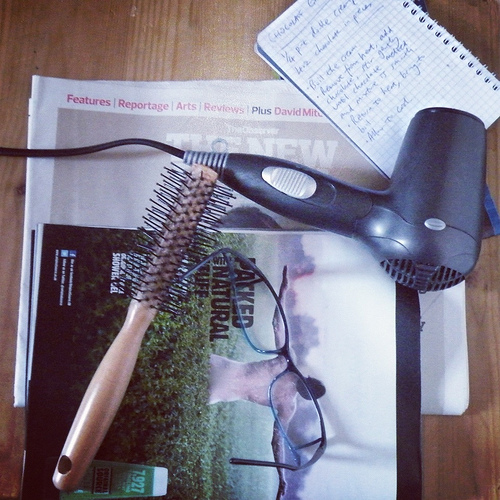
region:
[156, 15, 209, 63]
Small part of a wooden table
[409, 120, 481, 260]
Top black part of the hair blow dryer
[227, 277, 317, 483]
Blue and black glasses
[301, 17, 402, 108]
Writings on a small white notebook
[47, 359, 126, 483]
Bottom part of brush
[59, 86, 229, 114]
Red writings on the magazine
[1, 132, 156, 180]
Black cord of the hair blow dryer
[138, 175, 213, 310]
Top part of the tan brush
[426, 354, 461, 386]
White part of the magazine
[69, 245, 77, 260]
Facebook logo on magazines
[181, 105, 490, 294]
a black hair dryer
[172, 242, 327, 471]
a pair of black eyeglasses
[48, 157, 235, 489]
a brown hair brush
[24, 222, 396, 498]
a print magazine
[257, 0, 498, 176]
a small spiral note pad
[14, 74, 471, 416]
a folded print newspaper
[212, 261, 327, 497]
image of a naked man in bushes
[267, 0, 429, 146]
handwritten notes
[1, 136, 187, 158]
a black electric cord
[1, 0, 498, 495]
a brown table top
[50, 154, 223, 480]
Brown Hairbrush with black brissles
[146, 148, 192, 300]
Black brissles on hairbrush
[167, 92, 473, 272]
Black blowdryer with grey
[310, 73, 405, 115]
Blue ink writting on notepad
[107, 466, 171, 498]
Green numbers on magezine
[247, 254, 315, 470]
Blue prescription glasses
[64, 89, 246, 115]
Red Letters on magezine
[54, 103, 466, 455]
Person items on newspaper and magezine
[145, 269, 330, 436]
Half naked man on magezine cover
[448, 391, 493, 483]
Brown woodgrain on desk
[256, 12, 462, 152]
notes in a notebook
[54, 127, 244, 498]
brush on the table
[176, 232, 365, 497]
pair of blue glasses on the table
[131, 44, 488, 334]
black blow-dryer on the table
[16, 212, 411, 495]
magazine on the table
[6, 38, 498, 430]
newspaper on the table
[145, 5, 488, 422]
notebook on the table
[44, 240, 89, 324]
logos on the magazine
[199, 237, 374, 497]
man on the front of the magazine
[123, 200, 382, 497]
glasses on the top of magazine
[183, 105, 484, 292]
a black blow drier on the table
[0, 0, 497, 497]
a wooden table top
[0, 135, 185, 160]
a black electrical cord on the hair dryer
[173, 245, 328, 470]
a pair of glasses on the table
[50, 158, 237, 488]
a hair brush on the table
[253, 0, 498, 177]
a notebook on the table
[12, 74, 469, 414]
a newspaper on the table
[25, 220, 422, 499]
a magazine on the table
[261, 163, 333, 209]
switch on the hair dryer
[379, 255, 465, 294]
back vent on the hair dryer